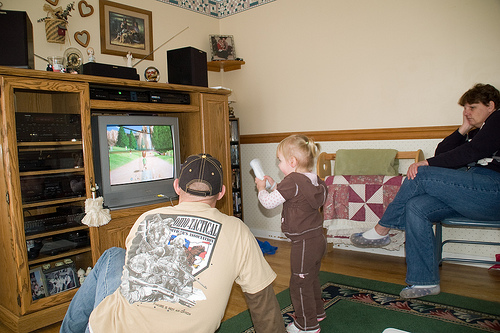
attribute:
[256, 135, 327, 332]
girl — young, little, playing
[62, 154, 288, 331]
man — sitting, watching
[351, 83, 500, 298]
woman — watching, sitting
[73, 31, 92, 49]
hearts — shaped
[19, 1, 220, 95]
wall — decorated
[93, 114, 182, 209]
television — silver, small, displaying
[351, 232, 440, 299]
slippers — gray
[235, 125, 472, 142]
border — wood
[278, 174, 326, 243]
shirt — brown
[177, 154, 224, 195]
hat — brown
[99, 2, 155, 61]
picture — brown, framed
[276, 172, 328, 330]
clothes — brown